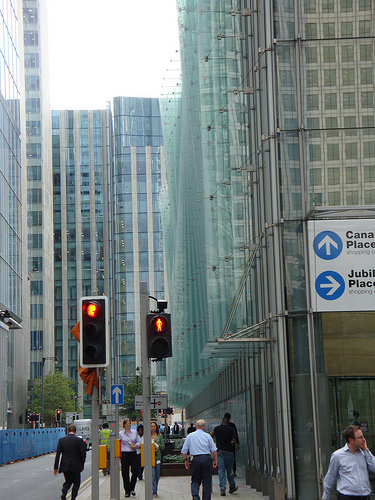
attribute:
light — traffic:
[73, 294, 111, 371]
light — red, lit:
[81, 301, 102, 322]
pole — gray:
[86, 372, 105, 498]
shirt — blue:
[178, 430, 220, 459]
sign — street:
[299, 213, 373, 317]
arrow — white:
[320, 233, 339, 256]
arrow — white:
[314, 272, 343, 299]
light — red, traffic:
[76, 293, 108, 376]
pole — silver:
[75, 294, 112, 498]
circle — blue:
[310, 229, 347, 259]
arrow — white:
[316, 233, 337, 255]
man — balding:
[178, 416, 223, 498]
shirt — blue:
[181, 428, 219, 455]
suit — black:
[56, 432, 85, 490]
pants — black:
[119, 448, 141, 491]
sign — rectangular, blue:
[101, 376, 129, 416]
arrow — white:
[111, 385, 121, 402]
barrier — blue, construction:
[2, 424, 57, 460]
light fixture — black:
[138, 305, 183, 366]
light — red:
[153, 317, 165, 332]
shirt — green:
[148, 432, 165, 460]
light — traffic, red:
[81, 294, 108, 373]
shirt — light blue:
[324, 445, 374, 493]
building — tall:
[55, 102, 121, 418]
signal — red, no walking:
[149, 315, 168, 333]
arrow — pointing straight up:
[312, 231, 344, 260]